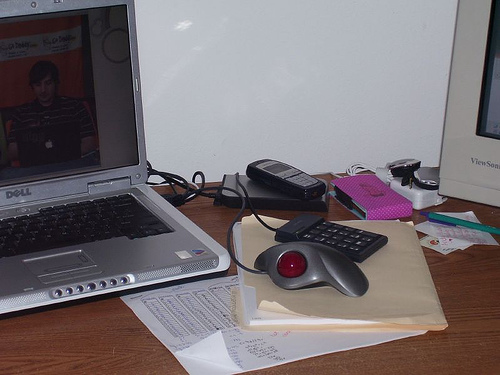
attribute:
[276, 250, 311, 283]
ball — red, shiny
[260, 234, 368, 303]
mouse — silver, large, gray, stationary, red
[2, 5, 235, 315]
computer — open, dell, silver, grey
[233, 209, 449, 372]
file folder — manila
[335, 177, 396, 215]
case — pink, hot pink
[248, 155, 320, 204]
phone — old, black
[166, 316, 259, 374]
paper — folded, white, turned up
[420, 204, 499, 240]
pen — aqua, blue, dark blue, turquoise, purple, green, thin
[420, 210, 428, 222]
blue — dark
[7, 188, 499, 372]
desk — wooden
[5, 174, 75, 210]
dell — silver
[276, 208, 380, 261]
keypad — black, white, numeric, external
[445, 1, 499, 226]
monitor — white, computer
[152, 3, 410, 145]
wall — painted, white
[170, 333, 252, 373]
edge — turned up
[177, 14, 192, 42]
spot — small